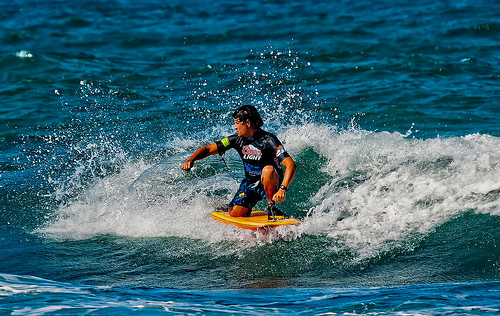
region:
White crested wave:
[342, 88, 497, 269]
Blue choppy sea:
[7, 0, 496, 84]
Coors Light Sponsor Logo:
[231, 140, 271, 167]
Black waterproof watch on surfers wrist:
[276, 172, 291, 199]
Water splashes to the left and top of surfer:
[33, 39, 345, 181]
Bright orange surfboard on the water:
[208, 193, 306, 243]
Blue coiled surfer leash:
[208, 132, 284, 222]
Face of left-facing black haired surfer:
[221, 98, 291, 143]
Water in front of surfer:
[144, 213, 417, 314]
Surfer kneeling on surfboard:
[173, 82, 326, 238]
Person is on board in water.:
[197, 158, 320, 298]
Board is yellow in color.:
[196, 171, 318, 284]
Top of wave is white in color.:
[124, 129, 415, 311]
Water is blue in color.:
[85, 237, 207, 312]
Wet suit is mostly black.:
[213, 110, 295, 240]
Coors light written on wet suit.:
[238, 136, 267, 184]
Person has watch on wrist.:
[276, 177, 293, 210]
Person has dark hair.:
[231, 92, 265, 152]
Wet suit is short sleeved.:
[194, 107, 329, 232]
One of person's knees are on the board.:
[223, 183, 292, 268]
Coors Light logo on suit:
[151, 84, 329, 248]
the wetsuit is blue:
[163, 65, 345, 270]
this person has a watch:
[132, 28, 354, 254]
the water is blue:
[152, 60, 418, 309]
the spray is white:
[123, 42, 417, 310]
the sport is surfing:
[152, 57, 344, 239]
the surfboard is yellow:
[148, 63, 341, 251]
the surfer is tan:
[146, 65, 388, 277]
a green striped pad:
[203, 102, 237, 157]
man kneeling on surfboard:
[177, 98, 309, 248]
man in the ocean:
[169, 99, 303, 229]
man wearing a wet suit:
[177, 101, 308, 228]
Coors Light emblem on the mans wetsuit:
[234, 137, 269, 168]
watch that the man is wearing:
[277, 182, 287, 192]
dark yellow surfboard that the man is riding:
[207, 196, 302, 238]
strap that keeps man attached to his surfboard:
[262, 205, 286, 221]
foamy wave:
[362, 127, 479, 262]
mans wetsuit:
[216, 124, 290, 210]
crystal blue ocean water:
[104, 25, 421, 89]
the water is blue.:
[12, 3, 459, 125]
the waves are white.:
[260, 68, 460, 223]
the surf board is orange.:
[200, 168, 347, 263]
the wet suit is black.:
[180, 106, 300, 213]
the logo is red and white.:
[225, 134, 265, 169]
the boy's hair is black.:
[219, 97, 270, 152]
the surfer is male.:
[162, 77, 289, 233]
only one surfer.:
[80, 34, 435, 265]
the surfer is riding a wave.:
[152, 72, 323, 257]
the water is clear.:
[116, 43, 456, 297]